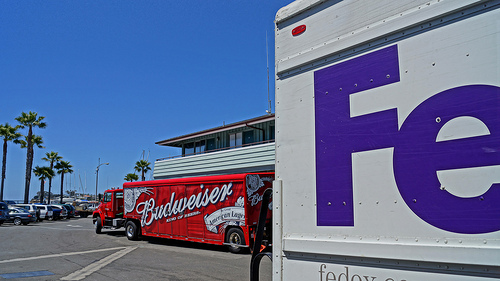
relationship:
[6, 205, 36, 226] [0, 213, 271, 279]
car in parking lot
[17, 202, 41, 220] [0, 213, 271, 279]
car in parking lot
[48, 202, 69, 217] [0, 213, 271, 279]
car in parking lot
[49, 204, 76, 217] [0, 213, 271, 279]
car in parking lot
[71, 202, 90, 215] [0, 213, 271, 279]
car in parking lot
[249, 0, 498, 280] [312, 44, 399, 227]
truck has f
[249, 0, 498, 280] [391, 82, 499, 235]
truck has letter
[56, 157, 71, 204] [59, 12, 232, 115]
palm tree against blue sky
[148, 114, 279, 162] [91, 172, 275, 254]
building behind beer truck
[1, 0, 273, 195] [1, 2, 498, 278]
sky in photo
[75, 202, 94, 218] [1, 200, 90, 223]
car in parking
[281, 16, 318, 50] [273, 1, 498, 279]
reflector on truck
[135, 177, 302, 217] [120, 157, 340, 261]
letters on truck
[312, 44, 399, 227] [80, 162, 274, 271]
f on truck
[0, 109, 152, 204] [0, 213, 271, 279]
palms next to parking lot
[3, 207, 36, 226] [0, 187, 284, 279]
car in parking lot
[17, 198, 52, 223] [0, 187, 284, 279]
car in parking lot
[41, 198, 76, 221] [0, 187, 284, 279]
car in parking lot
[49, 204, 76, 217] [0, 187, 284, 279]
car in parking lot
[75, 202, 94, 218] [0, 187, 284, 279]
car in parking lot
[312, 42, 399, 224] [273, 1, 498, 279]
f on truck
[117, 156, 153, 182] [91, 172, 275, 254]
pines behind beer truck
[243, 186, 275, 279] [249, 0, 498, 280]
door handle attached to back of truck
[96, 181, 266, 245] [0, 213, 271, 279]
beer truck in parking lot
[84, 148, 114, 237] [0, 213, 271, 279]
light near parking lot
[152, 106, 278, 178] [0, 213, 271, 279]
hotel beside parking lot